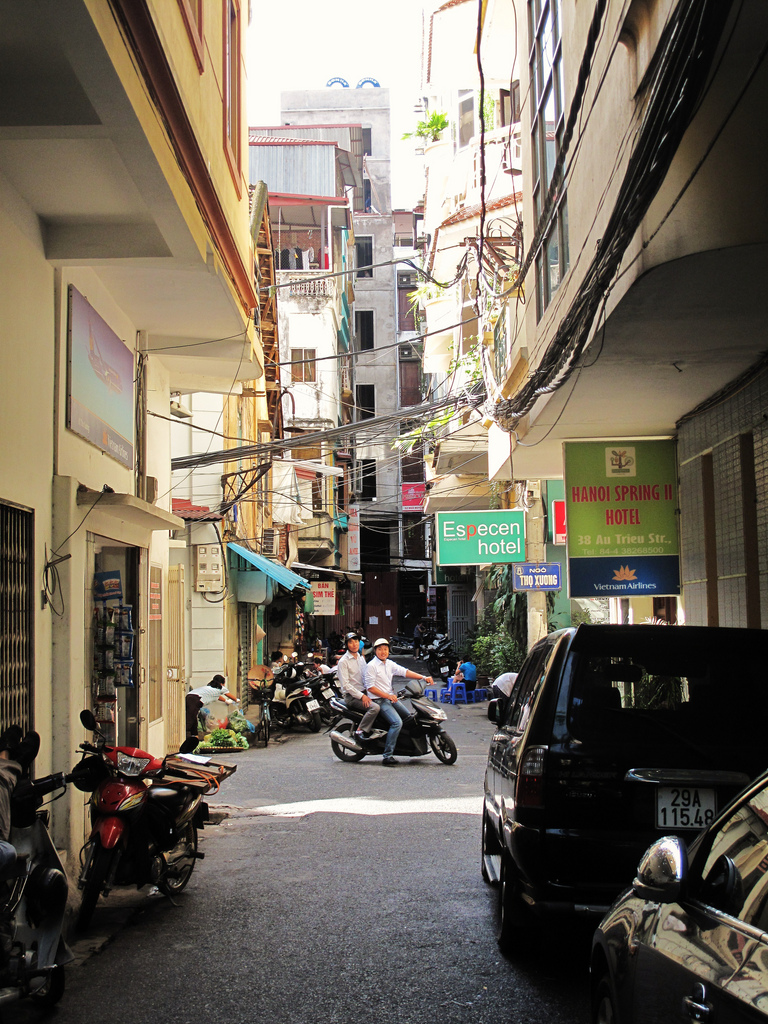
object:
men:
[323, 632, 459, 767]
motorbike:
[323, 677, 459, 765]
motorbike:
[74, 709, 236, 911]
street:
[204, 756, 488, 847]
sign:
[562, 438, 684, 599]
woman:
[186, 674, 242, 739]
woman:
[441, 654, 476, 697]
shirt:
[458, 662, 477, 682]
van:
[481, 621, 766, 941]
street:
[51, 654, 611, 1021]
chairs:
[424, 677, 488, 705]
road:
[171, 655, 562, 1017]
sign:
[435, 509, 526, 567]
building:
[248, 124, 364, 570]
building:
[280, 87, 401, 522]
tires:
[497, 868, 514, 950]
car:
[592, 770, 767, 1020]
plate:
[658, 788, 716, 829]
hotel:
[481, 0, 767, 629]